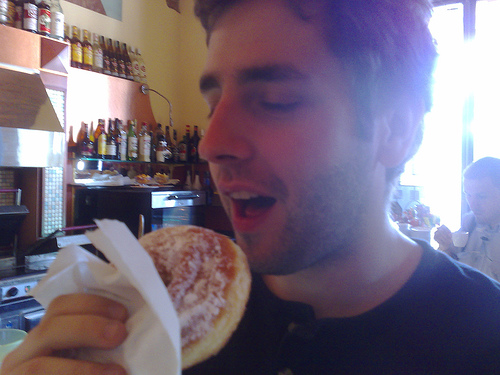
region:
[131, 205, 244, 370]
Donut covered with sugar.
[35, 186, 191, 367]
White napkin around the donut.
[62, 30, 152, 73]
Many bottles on the shelf.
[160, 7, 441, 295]
Man about to eat a donut.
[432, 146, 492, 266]
Man having a cup of coffee.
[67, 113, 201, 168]
Condiments on the shelf.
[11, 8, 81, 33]
Bottles and cans on the shelf.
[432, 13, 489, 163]
Sunlight streaming through the window.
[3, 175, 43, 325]
Restaurant grade grill against the wall.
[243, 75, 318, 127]
Man with his eye closed.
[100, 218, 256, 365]
sugar crusted yeast doughnut being eaten by man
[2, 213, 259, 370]
white hand of man holding sugar doughnut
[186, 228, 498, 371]
man wearing round necked black shirt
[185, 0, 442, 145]
salt and pepper hair on man's head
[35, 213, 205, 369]
white paper surrounding doughnut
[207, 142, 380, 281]
three o clock shadow on man's face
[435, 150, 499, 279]
man in background holding white coffee cup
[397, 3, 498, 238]
bright white sun streaming through windows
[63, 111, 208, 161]
shelf of coffee syrups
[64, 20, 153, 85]
shelf of coffee syrups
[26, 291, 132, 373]
The mans hand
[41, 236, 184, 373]
The napkin that is around the doughnut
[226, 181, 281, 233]
The mans open mouth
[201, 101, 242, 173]
The mans big nose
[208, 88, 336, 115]
The mans closed eyes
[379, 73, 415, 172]
The mans ear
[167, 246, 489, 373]
The mans black t shirt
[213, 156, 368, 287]
The mans beard growing in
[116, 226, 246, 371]
The doughnut in the mans hand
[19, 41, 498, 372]
A man standing around eating a doughnut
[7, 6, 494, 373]
man eating a donut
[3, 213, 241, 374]
hand holding a donut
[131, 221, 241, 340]
donut covered with sugar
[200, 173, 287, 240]
the mouth is open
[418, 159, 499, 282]
man holding a cup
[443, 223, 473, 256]
the cup is white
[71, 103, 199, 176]
bottles above an oven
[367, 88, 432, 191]
the ear of man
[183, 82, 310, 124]
eyes of man are closed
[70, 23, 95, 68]
bottles with yellow label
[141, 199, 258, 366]
doughnut in man's hand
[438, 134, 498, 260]
patron in a restaurant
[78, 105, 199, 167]
drink bottles on a shelf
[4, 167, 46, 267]
oven in a restaurant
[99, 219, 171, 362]
white napkin on a doughnut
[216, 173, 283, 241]
mouth on a man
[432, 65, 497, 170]
sunlight shining through a window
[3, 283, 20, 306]
knob on an appliance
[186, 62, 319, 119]
eyes of a man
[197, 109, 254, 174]
nose of a man